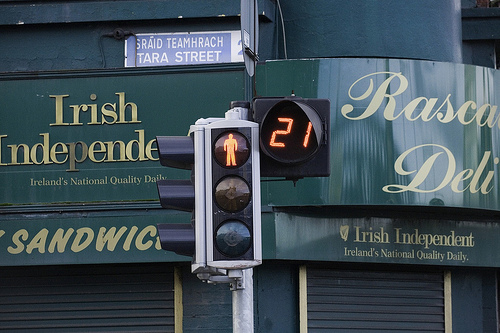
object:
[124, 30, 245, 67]
sign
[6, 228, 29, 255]
letter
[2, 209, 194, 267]
sign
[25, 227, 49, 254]
letter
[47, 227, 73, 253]
letter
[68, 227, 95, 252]
letter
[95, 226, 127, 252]
letter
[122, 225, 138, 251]
letter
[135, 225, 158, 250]
letter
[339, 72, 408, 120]
letter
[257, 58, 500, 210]
sign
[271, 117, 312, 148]
number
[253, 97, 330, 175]
sign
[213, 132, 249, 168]
light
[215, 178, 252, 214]
light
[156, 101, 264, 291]
traffic light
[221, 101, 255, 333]
pole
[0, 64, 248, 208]
sign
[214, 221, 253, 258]
light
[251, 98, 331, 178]
timer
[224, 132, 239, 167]
man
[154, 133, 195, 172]
cover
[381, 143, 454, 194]
lettering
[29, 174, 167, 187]
lettering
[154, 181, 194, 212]
cover